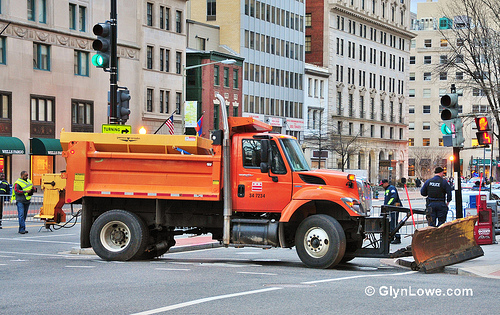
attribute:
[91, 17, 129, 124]
traffic light — green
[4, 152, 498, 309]
street — level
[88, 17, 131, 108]
light — green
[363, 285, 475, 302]
letters — white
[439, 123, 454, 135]
light — green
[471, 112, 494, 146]
stop hand — illuminated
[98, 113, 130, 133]
sign — Neon, yellow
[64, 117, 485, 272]
vehicle — rusted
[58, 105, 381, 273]
truck — orange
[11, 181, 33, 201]
vest — yellow, reflective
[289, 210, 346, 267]
wheel — black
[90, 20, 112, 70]
light fixture — Black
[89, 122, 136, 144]
sign — yellow, traffic sign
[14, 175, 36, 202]
vest — yellow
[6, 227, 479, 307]
ground — gray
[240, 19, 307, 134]
building — gray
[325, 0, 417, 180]
building — high rise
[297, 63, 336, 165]
building — high rise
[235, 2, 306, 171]
building — high rise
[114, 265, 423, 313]
lines — white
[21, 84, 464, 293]
truck — orange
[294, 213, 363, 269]
wheel — black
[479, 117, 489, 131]
hand — orange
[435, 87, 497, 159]
walking sign — black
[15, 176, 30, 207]
vest — yellow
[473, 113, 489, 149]
hand — illuminated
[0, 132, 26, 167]
awning — green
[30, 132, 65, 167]
awning — green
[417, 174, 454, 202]
shirt — dark blue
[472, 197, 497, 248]
newspaper dispensor — red